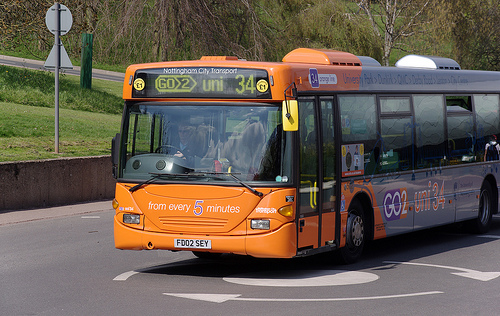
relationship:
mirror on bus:
[278, 92, 297, 131] [188, 73, 372, 199]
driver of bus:
[227, 128, 274, 167] [188, 73, 372, 199]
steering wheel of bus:
[210, 148, 251, 172] [188, 73, 372, 199]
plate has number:
[178, 229, 223, 259] [188, 191, 221, 229]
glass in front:
[163, 123, 242, 169] [135, 74, 265, 225]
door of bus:
[291, 94, 333, 246] [188, 73, 372, 199]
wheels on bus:
[321, 186, 498, 253] [188, 73, 372, 199]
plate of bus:
[178, 229, 223, 259] [188, 73, 372, 199]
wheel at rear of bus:
[345, 195, 377, 234] [93, 43, 498, 273]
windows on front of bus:
[356, 109, 467, 180] [93, 43, 498, 273]